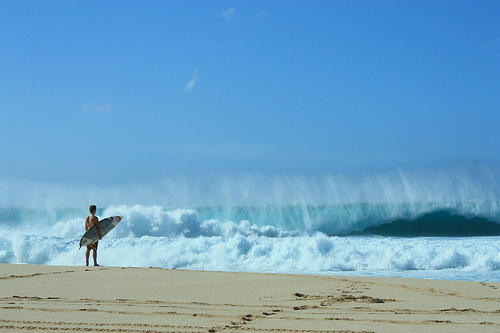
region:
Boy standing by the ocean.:
[83, 198, 117, 263]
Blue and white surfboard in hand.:
[84, 227, 131, 242]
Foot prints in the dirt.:
[261, 285, 376, 331]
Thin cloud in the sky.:
[173, 67, 208, 108]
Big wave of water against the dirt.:
[166, 207, 308, 262]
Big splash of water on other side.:
[317, 173, 492, 235]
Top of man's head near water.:
[79, 202, 102, 215]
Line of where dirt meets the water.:
[198, 250, 316, 285]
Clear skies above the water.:
[305, 50, 496, 119]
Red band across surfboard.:
[113, 213, 128, 229]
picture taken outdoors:
[22, 15, 492, 296]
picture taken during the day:
[67, 49, 490, 329]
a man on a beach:
[77, 213, 122, 270]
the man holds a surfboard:
[63, 191, 161, 303]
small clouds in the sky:
[174, 21, 220, 93]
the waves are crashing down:
[247, 228, 452, 273]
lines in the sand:
[173, 288, 248, 322]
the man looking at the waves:
[58, 181, 182, 260]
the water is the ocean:
[217, 196, 445, 286]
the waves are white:
[143, 212, 338, 286]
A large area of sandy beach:
[0, 261, 499, 331]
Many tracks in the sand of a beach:
[2, 264, 499, 330]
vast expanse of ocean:
[1, 203, 498, 277]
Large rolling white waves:
[2, 203, 499, 274]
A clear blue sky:
[4, 1, 499, 200]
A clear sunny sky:
[2, 3, 499, 203]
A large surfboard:
[77, 215, 121, 249]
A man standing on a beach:
[85, 203, 101, 268]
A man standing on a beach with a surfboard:
[76, 205, 121, 268]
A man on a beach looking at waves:
[77, 204, 122, 268]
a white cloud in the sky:
[178, 70, 198, 101]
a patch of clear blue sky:
[316, 34, 405, 112]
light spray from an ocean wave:
[229, 179, 353, 218]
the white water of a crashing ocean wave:
[128, 210, 198, 239]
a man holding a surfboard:
[70, 203, 128, 267]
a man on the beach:
[70, 198, 121, 293]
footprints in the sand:
[226, 302, 290, 331]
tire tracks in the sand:
[58, 305, 96, 330]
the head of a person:
[87, 200, 97, 215]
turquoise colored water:
[402, 215, 451, 236]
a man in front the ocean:
[14, 165, 421, 282]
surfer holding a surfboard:
[67, 191, 133, 271]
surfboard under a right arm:
[74, 203, 129, 265]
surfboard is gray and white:
[74, 210, 126, 254]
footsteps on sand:
[188, 274, 404, 331]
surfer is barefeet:
[76, 202, 126, 276]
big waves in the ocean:
[4, 185, 494, 276]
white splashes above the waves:
[24, 168, 495, 235]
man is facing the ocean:
[71, 192, 113, 272]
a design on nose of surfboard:
[111, 208, 128, 228]